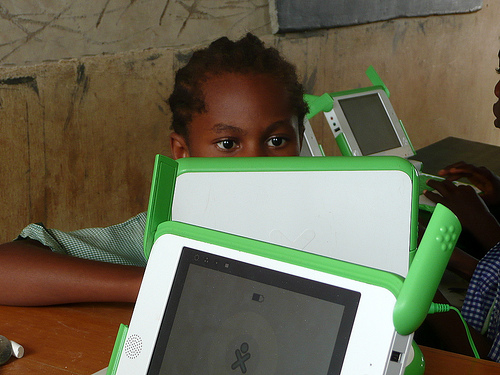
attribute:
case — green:
[121, 212, 404, 370]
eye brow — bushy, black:
[209, 125, 243, 133]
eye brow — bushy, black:
[264, 120, 293, 135]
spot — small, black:
[369, 363, 373, 368]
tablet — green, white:
[110, 218, 414, 374]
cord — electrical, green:
[431, 297, 483, 363]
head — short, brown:
[170, 34, 308, 161]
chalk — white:
[10, 340, 24, 358]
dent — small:
[1, 74, 41, 91]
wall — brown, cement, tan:
[0, 1, 496, 245]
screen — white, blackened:
[273, 0, 488, 36]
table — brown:
[393, 137, 498, 215]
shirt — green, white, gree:
[27, 178, 379, 266]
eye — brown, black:
[221, 140, 236, 146]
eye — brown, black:
[273, 138, 282, 143]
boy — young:
[0, 33, 396, 306]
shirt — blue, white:
[461, 244, 499, 369]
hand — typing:
[443, 164, 499, 205]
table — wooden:
[0, 251, 499, 372]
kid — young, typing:
[412, 46, 498, 358]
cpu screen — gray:
[151, 265, 343, 374]